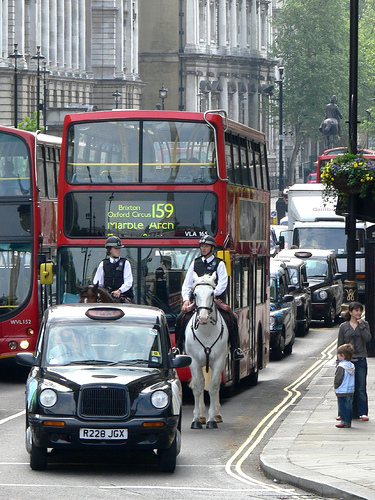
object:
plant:
[321, 152, 374, 215]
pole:
[344, 1, 360, 278]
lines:
[227, 340, 336, 461]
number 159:
[151, 202, 174, 219]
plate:
[80, 426, 128, 441]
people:
[336, 300, 371, 422]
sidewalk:
[259, 355, 375, 498]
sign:
[106, 202, 174, 231]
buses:
[0, 125, 63, 367]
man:
[172, 234, 246, 359]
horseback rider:
[322, 95, 344, 137]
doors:
[247, 256, 254, 369]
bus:
[56, 108, 271, 397]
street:
[0, 391, 297, 499]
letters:
[82, 428, 88, 436]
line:
[221, 463, 306, 498]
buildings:
[0, 0, 145, 137]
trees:
[259, 0, 347, 185]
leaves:
[284, 5, 296, 26]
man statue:
[323, 93, 344, 137]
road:
[0, 382, 259, 497]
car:
[269, 265, 295, 360]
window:
[64, 116, 141, 185]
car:
[15, 303, 193, 471]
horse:
[319, 117, 341, 150]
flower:
[352, 161, 359, 169]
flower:
[357, 159, 364, 166]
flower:
[330, 175, 335, 182]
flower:
[364, 175, 371, 181]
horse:
[183, 270, 229, 429]